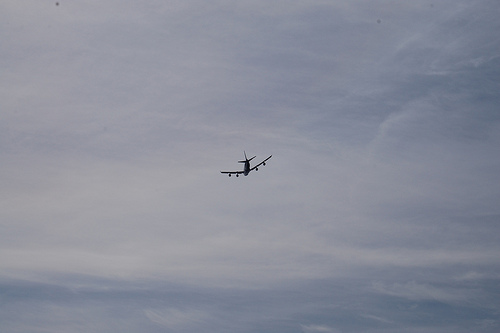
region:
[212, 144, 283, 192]
plane in the sky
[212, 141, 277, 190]
plane flying in the sky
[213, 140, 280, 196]
plane cruising in the sky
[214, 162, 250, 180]
wing of a plane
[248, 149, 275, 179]
wing of a plane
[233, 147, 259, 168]
tail section of a plane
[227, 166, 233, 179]
engine of a plane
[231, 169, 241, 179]
engine of a plane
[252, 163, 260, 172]
engine of a plane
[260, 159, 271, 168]
engine of a plane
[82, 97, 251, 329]
the sky is blue and clear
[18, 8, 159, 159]
the sky is blue and clear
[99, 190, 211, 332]
the sky is blue and clear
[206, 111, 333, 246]
the plane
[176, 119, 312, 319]
the plane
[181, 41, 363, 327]
the plane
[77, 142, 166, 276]
the clouds are thin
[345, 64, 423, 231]
the clouds are white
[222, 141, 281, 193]
the plane is tilted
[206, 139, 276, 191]
the plane is flying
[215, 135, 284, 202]
the plane is in the sky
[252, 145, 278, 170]
the plane has a right wing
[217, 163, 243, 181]
the plane has a left wing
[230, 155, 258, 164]
the plane has horazantel stabilizers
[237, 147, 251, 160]
the plane has vertical stablizer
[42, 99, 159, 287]
the sky is cloudy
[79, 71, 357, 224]
the plane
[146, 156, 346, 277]
the plane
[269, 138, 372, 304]
the plane